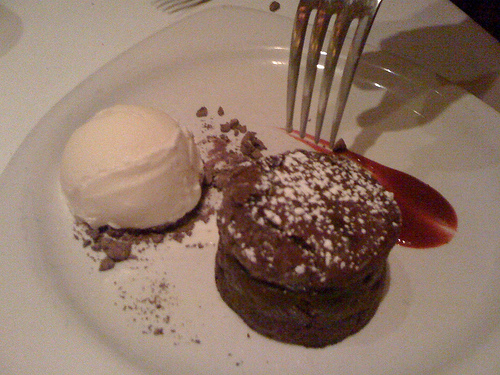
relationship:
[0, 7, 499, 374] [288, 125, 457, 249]
plate has sauce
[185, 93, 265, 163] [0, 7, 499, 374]
crumbs are  on plate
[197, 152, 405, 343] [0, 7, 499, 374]
brownie on plate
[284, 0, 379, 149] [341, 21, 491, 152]
fork has shadow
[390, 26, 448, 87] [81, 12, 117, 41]
shadow on table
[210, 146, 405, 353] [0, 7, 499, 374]
brownie on a plate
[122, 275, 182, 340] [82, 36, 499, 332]
crumbs on a plate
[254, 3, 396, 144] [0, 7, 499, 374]
fork on a plate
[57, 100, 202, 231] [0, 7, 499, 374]
ice cream on plate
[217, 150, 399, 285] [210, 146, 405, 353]
powder on brownie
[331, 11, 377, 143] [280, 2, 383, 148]
prongs of fork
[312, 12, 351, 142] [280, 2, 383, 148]
prongs of fork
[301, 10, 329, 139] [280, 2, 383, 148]
prongs of fork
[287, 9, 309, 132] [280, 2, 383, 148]
prongs of fork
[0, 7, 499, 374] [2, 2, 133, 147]
plate on table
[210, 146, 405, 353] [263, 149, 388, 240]
brownie has powder